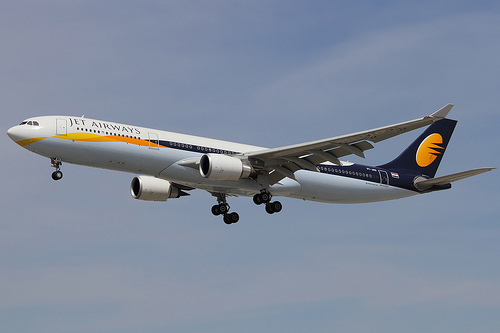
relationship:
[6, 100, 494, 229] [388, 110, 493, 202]
airplane has tail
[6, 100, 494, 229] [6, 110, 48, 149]
airplane has cockpit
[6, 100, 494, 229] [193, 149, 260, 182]
airplane has engine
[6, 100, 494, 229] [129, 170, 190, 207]
airplane has engine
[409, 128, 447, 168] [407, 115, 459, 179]
logo on background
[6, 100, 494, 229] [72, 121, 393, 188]
airplane has windows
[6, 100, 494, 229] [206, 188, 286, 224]
airplane has wheels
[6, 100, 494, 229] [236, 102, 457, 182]
airplane has wing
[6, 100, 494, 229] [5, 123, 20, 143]
airplane has tip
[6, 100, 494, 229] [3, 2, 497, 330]
airplane in sky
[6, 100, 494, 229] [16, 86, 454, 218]
airplane flying passengers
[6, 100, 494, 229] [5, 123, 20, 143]
airplane has nose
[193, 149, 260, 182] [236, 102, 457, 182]
engine on wing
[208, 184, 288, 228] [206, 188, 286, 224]
landing gear has wheels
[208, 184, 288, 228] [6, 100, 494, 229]
landing gear under airplane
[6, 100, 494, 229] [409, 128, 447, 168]
airplane has logo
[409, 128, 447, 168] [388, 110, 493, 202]
logo on tail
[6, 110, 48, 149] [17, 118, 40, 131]
cockpit has windows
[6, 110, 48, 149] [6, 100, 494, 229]
cockpit in front of airplane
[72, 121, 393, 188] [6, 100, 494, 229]
windows on airplane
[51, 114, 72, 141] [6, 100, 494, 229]
door on airplane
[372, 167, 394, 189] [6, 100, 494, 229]
door on airplane